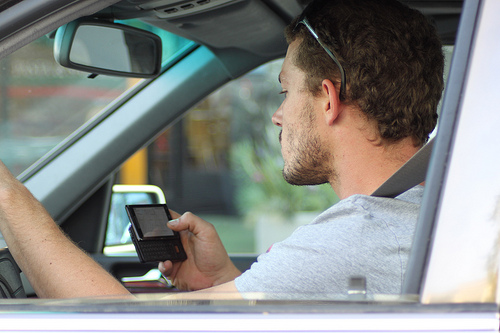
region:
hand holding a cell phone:
[119, 193, 211, 266]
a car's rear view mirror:
[47, 7, 174, 90]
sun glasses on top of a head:
[281, 5, 353, 91]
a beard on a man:
[280, 99, 331, 192]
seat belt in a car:
[356, 119, 445, 214]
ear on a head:
[313, 77, 347, 124]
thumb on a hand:
[159, 202, 224, 243]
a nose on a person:
[263, 99, 290, 130]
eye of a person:
[264, 74, 300, 99]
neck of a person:
[330, 150, 435, 202]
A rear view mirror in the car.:
[43, 18, 171, 95]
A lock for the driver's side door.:
[337, 267, 379, 310]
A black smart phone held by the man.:
[115, 194, 197, 269]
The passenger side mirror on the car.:
[93, 172, 178, 257]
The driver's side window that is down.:
[0, 3, 486, 300]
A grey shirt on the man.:
[232, 181, 436, 298]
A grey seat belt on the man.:
[347, 126, 447, 213]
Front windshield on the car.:
[0, 11, 217, 190]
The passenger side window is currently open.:
[94, 26, 459, 259]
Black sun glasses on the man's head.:
[272, 3, 358, 118]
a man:
[31, 7, 486, 327]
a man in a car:
[8, 7, 498, 297]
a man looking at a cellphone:
[23, 6, 473, 328]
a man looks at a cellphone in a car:
[16, 2, 444, 312]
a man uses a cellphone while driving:
[31, 5, 486, 317]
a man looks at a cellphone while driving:
[23, 10, 436, 301]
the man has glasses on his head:
[63, 4, 460, 299]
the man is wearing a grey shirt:
[50, 14, 455, 327]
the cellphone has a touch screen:
[111, 189, 220, 283]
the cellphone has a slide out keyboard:
[98, 188, 271, 330]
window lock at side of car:
[331, 267, 378, 310]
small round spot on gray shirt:
[355, 214, 390, 228]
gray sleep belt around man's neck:
[348, 160, 430, 214]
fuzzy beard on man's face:
[274, 140, 347, 186]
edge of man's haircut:
[348, 120, 415, 170]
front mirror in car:
[48, 18, 175, 93]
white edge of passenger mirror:
[83, 164, 186, 247]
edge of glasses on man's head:
[282, 11, 373, 104]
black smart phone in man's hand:
[128, 195, 194, 255]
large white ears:
[313, 72, 348, 123]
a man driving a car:
[28, 12, 487, 315]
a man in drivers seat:
[21, 0, 485, 307]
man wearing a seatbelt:
[24, 8, 485, 295]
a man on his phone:
[51, 0, 480, 317]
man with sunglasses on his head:
[256, 0, 452, 197]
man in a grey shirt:
[196, 5, 476, 312]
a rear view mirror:
[39, 0, 191, 93]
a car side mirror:
[96, 162, 188, 257]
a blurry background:
[79, 101, 281, 266]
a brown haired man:
[251, 0, 473, 253]